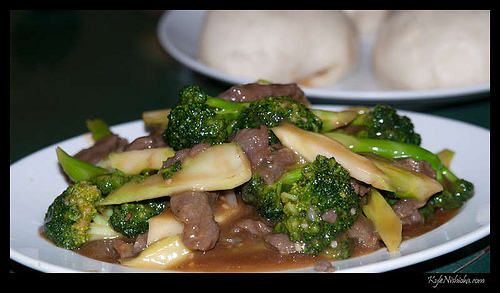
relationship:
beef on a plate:
[170, 191, 221, 252] [9, 103, 490, 273]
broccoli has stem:
[271, 156, 374, 253] [210, 97, 252, 134]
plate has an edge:
[9, 103, 490, 273] [13, 140, 57, 162]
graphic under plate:
[428, 274, 485, 292] [9, 103, 490, 273]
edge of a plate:
[13, 140, 57, 162] [9, 103, 490, 273]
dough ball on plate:
[194, 13, 361, 84] [161, 10, 496, 101]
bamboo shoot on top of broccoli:
[273, 121, 396, 197] [271, 156, 374, 253]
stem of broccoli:
[210, 97, 252, 134] [271, 156, 374, 253]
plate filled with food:
[9, 103, 490, 273] [74, 82, 426, 246]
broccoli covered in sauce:
[271, 156, 374, 253] [199, 235, 297, 272]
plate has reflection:
[9, 103, 490, 273] [21, 240, 63, 268]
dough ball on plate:
[194, 13, 361, 84] [9, 103, 490, 273]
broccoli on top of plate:
[271, 156, 374, 253] [9, 103, 490, 273]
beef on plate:
[170, 191, 221, 252] [9, 103, 490, 273]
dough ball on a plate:
[194, 13, 361, 84] [161, 10, 496, 101]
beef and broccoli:
[170, 191, 221, 252] [271, 156, 374, 253]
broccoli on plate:
[271, 156, 374, 253] [9, 103, 490, 273]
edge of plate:
[13, 140, 57, 162] [9, 103, 490, 273]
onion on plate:
[226, 192, 240, 211] [9, 103, 490, 273]